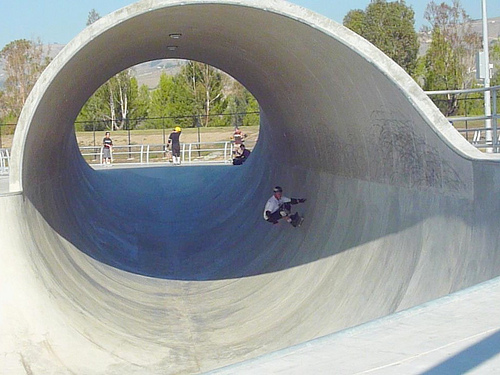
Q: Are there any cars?
A: No, there are no cars.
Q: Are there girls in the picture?
A: No, there are no girls.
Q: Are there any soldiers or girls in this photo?
A: No, there are no girls or soldiers.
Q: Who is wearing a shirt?
A: The man is wearing a shirt.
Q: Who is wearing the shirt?
A: The man is wearing a shirt.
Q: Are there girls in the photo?
A: No, there are no girls.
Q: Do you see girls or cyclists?
A: No, there are no girls or cyclists.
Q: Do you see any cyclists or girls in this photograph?
A: No, there are no girls or cyclists.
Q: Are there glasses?
A: No, there are no glasses.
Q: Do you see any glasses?
A: No, there are no glasses.